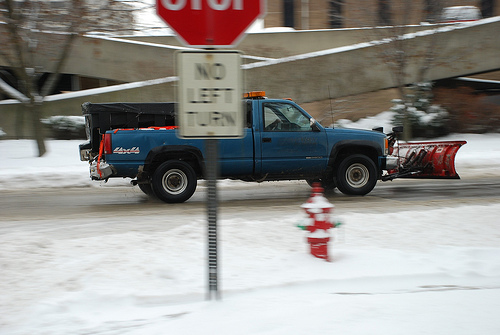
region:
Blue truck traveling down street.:
[76, 92, 394, 205]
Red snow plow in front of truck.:
[387, 131, 469, 195]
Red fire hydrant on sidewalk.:
[288, 181, 354, 268]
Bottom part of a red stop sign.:
[153, 2, 274, 50]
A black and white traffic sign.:
[165, 46, 264, 303]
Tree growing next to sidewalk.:
[7, 5, 125, 172]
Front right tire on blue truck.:
[333, 150, 383, 199]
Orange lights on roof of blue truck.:
[246, 86, 272, 103]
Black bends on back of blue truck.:
[73, 96, 184, 162]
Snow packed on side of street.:
[21, 230, 193, 317]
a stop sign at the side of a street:
[152, 1, 282, 296]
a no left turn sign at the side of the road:
[171, 45, 247, 305]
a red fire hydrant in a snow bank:
[160, 20, 352, 296]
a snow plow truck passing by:
[77, 91, 469, 198]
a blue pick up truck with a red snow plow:
[85, 86, 470, 197]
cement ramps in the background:
[5, 2, 497, 144]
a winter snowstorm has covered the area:
[5, 40, 495, 326]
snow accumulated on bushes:
[326, 90, 448, 137]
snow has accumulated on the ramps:
[10, 10, 497, 97]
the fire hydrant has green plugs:
[293, 181, 347, 266]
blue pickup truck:
[66, 80, 408, 217]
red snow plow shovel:
[386, 127, 471, 194]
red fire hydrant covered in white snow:
[292, 177, 347, 269]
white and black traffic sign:
[167, 39, 254, 149]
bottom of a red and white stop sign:
[147, 0, 279, 58]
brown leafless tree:
[0, 0, 142, 157]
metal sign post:
[205, 139, 224, 302]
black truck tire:
[330, 150, 383, 198]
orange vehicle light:
[240, 81, 267, 103]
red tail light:
[99, 130, 119, 156]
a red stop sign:
[161, 1, 275, 48]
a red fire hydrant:
[277, 174, 360, 306]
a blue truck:
[67, 57, 459, 216]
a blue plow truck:
[83, 70, 448, 198]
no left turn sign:
[163, 40, 256, 143]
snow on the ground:
[11, 114, 474, 319]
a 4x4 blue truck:
[95, 64, 366, 194]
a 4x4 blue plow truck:
[106, 75, 458, 208]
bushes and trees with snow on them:
[363, 75, 490, 150]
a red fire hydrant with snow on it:
[288, 176, 385, 297]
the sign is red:
[152, 1, 274, 52]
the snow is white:
[58, 217, 132, 297]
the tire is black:
[150, 153, 201, 213]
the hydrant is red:
[296, 176, 352, 289]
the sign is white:
[174, 43, 254, 150]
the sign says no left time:
[167, 45, 254, 150]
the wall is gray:
[282, 47, 364, 101]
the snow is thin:
[67, 230, 150, 313]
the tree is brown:
[20, 16, 66, 157]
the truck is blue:
[51, 49, 422, 210]